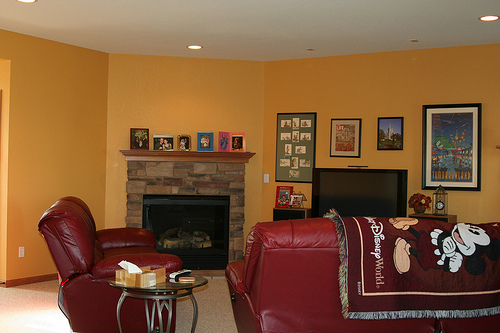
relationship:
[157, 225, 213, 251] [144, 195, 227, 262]
logs in fireplace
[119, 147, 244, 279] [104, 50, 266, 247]
firepace against wall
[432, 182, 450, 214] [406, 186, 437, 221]
birdcage by flowers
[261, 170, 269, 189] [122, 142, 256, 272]
lightswitch by fireplace